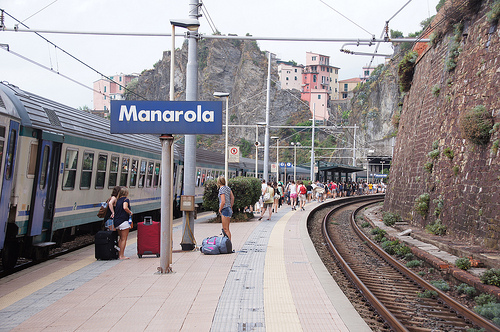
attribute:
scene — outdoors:
[0, 5, 498, 325]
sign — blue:
[107, 99, 224, 135]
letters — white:
[118, 103, 215, 126]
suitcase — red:
[135, 216, 162, 259]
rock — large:
[90, 10, 323, 162]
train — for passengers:
[2, 79, 289, 260]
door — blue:
[34, 136, 60, 240]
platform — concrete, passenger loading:
[16, 188, 371, 330]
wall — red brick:
[385, 15, 498, 255]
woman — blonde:
[206, 166, 242, 251]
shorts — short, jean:
[217, 206, 233, 220]